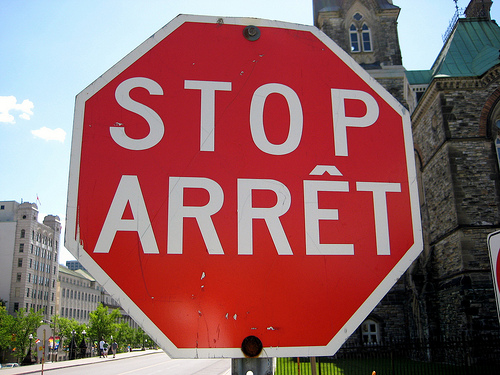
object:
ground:
[0, 350, 278, 375]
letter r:
[235, 178, 293, 255]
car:
[2, 360, 22, 368]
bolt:
[239, 335, 264, 356]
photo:
[0, 0, 500, 375]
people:
[81, 337, 103, 360]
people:
[103, 340, 110, 358]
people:
[98, 335, 105, 356]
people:
[110, 339, 118, 358]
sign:
[61, 13, 422, 361]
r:
[165, 174, 225, 259]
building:
[307, 0, 500, 375]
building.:
[251, 14, 498, 373]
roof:
[308, 0, 500, 128]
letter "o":
[248, 81, 303, 156]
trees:
[0, 299, 161, 368]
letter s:
[107, 74, 167, 152]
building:
[0, 199, 156, 364]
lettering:
[92, 77, 402, 257]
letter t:
[180, 78, 233, 152]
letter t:
[354, 182, 402, 255]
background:
[0, 190, 158, 375]